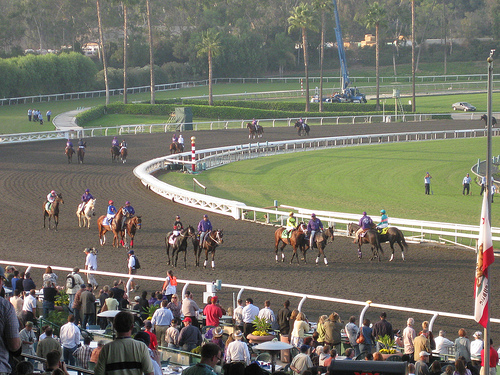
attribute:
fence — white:
[37, 95, 62, 101]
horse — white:
[76, 199, 97, 227]